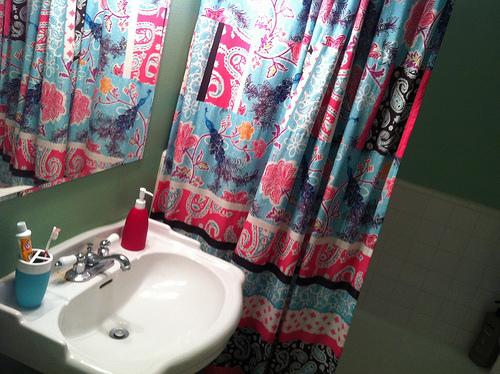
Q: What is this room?
A: A bathroom.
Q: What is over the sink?
A: A mirror.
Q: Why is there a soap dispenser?
A: To wash hands.